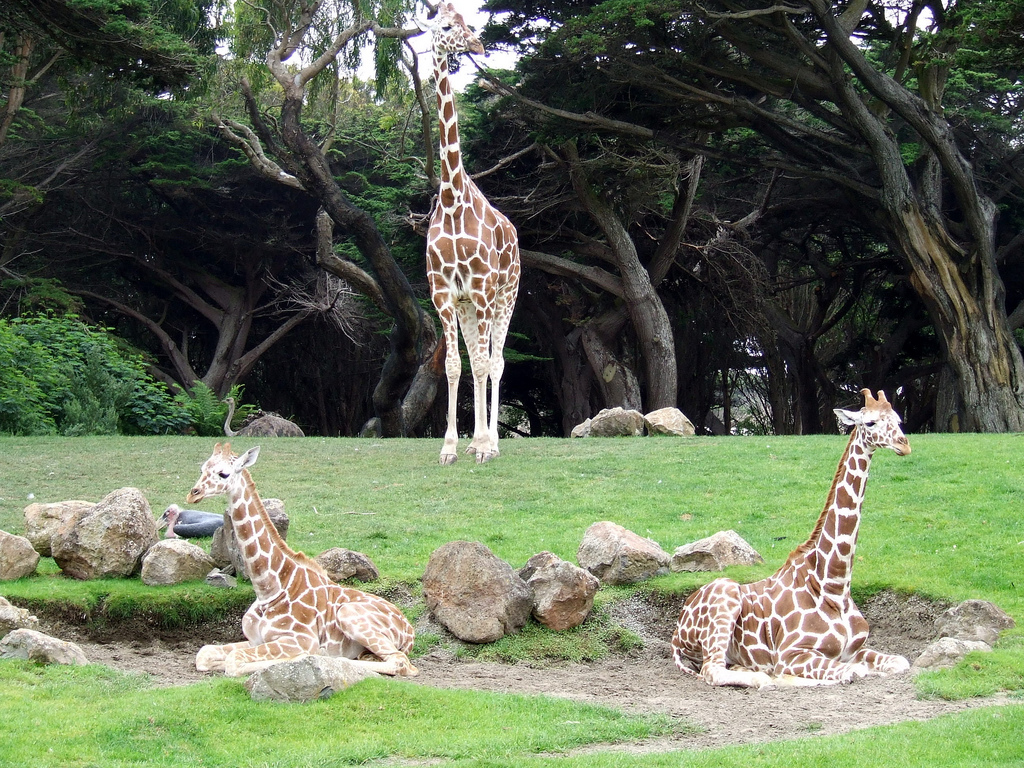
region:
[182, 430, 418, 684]
a brown and white spotted giraffe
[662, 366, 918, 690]
a brown and white spotted giraffe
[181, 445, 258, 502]
the head of a brown and white spotted giraffe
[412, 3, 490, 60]
the head of a brown and white spotted giraffe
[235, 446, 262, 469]
the white ear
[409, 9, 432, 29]
the white ear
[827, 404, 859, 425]
the white ear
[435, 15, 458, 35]
Giraffe has large dark eye.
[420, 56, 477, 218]
Giraffe has long neck.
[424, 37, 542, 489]
Giraffe is standing in grassy area.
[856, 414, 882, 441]
Giraffe has large dark eye.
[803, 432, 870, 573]
Giraffe has long neck.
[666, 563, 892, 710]
Giraffe is sitting in dirt area.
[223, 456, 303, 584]
Giraffe has long neck.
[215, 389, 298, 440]
Brownish gray ostrich in distance.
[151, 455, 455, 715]
Giraffe is sitting in dark area.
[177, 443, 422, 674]
giraffe is laying on the ground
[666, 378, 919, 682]
giraffe is laying on the ground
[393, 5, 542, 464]
giraffe is standing up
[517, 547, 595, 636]
rock is on the grass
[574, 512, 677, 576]
rock is on the grass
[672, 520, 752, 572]
rock is on the grass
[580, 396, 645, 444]
rock is on the grass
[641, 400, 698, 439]
rock is on the grass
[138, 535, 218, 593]
rock is on the grass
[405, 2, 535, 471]
yellow and brown giraffe standing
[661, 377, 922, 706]
yellow and brown giraffe sitting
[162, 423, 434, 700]
yellow and brown giraffe sitting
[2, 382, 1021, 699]
giraffes sitting among rocks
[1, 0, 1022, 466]
giraffe standing in front of trees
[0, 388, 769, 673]
large grey rocks on grass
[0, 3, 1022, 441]
bright sky above dark forest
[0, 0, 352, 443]
bush near a tree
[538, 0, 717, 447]
grey rocks in front of trees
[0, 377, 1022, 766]
giraffes sitting in crater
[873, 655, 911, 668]
leg of the giraffe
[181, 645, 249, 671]
leg of the giraffe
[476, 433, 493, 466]
leg of the giraffe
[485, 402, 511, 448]
leg of the giraffe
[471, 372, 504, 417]
leg of the giraffe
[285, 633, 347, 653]
leg of the giraffe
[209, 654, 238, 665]
leg of the giraffe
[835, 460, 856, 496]
brown spot on the giraffe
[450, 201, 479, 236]
brown spot on the giraffe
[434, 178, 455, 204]
brown spot on the giraffe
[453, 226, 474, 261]
brown spot on the giraffe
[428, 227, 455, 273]
brown spot on the giraffe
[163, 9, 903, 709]
Giraffes in a field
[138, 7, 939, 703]
Giraffes in the grass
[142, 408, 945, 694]
Giraffes on the ground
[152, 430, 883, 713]
Giraffes seated on the ground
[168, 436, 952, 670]
Giraffes on the grass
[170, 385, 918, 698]
Giraffes seated on the grass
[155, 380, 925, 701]
Giraffes in front of rocks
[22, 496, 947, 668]
Rocks behind the giraffes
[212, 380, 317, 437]
Large bird near trees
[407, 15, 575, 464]
Giraffe standing in grass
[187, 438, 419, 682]
cream and brown giraffe sitting in the gray dirt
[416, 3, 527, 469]
cream and brown giraffe standing in the grass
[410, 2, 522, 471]
cream and brown giraffe looking toward the right